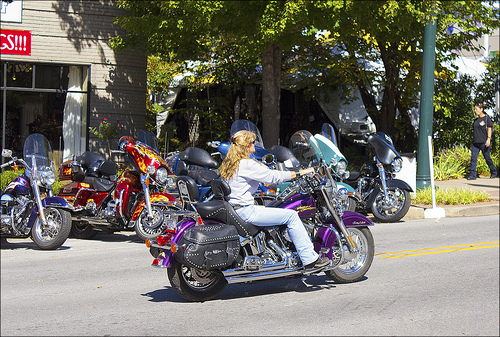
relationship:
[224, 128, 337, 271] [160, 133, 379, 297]
lady on bike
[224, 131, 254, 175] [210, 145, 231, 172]
lady has tail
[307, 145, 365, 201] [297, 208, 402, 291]
front of bike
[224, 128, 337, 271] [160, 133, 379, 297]
lady riding bike